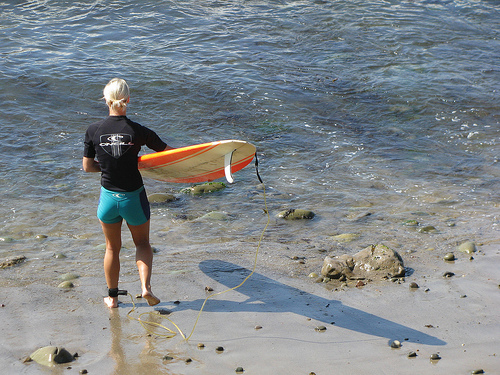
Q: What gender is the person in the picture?
A: Female.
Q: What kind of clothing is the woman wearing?
A: Surfer shorts and wetshirt.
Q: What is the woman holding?
A: Surfboard.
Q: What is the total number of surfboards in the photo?
A: 1.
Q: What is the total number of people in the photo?
A: 1.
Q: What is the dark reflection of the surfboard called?
A: A shadow.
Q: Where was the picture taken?
A: At the beach.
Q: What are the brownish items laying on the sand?
A: Rocks.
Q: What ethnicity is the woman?
A: Caucasian.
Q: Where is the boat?
A: There is no boat shown.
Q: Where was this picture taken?
A: Beach.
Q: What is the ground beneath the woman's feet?
A: Sand.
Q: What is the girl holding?
A: Surfboard.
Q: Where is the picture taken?
A: Beach.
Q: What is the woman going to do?
A: Go surfing.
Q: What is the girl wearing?
A: Black shirt.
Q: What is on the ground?
A: Chunks of sand.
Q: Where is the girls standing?
A: Near the water.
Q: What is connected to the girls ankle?
A: Surfboard.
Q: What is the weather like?
A: Sunny.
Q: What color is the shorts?
A: Aqua.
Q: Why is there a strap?
A: Maintain board.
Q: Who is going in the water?
A: A lady.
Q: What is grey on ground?
A: Rocks.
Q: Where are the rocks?
A: In water.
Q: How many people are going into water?
A: One.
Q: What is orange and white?
A: Surfboard.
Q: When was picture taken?
A: Daytime.